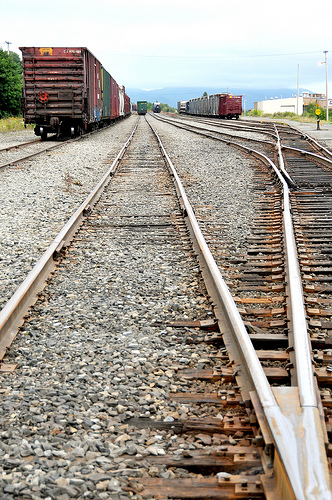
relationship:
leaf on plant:
[4, 75, 16, 81] [1, 51, 22, 117]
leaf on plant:
[9, 92, 12, 96] [0, 48, 18, 88]